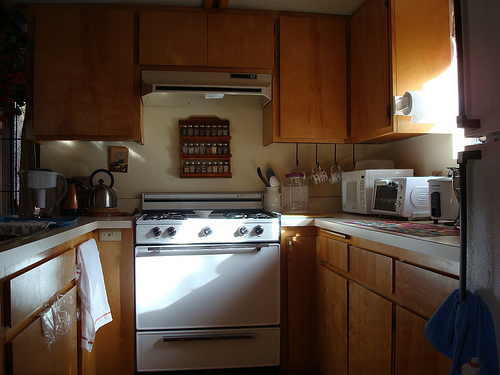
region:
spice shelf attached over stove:
[168, 102, 244, 186]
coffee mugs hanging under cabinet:
[301, 155, 374, 196]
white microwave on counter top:
[336, 160, 387, 211]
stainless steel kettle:
[76, 162, 133, 225]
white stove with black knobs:
[127, 170, 293, 374]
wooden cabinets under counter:
[285, 215, 453, 373]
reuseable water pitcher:
[11, 157, 76, 223]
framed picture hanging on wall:
[100, 140, 140, 180]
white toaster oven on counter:
[373, 172, 430, 225]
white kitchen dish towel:
[66, 234, 131, 351]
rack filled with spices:
[175, 109, 239, 186]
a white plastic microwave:
[339, 167, 411, 213]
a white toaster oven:
[369, 172, 441, 219]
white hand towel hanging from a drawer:
[71, 238, 113, 356]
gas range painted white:
[125, 188, 289, 373]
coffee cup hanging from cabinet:
[307, 161, 337, 188]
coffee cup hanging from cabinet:
[327, 163, 347, 184]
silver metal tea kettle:
[87, 163, 118, 213]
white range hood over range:
[137, 66, 276, 115]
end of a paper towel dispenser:
[392, 82, 433, 124]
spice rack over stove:
[163, 113, 248, 183]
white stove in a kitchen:
[119, 182, 309, 372]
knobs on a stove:
[150, 226, 282, 249]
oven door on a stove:
[124, 241, 286, 327]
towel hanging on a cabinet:
[66, 238, 118, 348]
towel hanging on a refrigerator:
[435, 261, 493, 365]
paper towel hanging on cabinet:
[395, 77, 466, 121]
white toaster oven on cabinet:
[371, 166, 436, 211]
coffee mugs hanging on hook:
[302, 156, 350, 194]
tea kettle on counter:
[85, 160, 126, 211]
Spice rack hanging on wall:
[172, 108, 239, 184]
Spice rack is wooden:
[174, 110, 239, 191]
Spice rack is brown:
[172, 109, 247, 184]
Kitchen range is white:
[136, 187, 293, 374]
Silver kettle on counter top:
[83, 160, 118, 217]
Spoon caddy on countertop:
[251, 157, 288, 217]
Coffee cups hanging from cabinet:
[311, 134, 345, 195]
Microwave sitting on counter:
[338, 159, 395, 221]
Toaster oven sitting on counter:
[367, 165, 429, 235]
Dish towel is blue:
[413, 242, 498, 367]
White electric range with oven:
[136, 195, 281, 370]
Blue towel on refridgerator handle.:
[408, 274, 498, 372]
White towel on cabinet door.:
[72, 239, 114, 352]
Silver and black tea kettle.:
[81, 164, 118, 217]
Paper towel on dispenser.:
[392, 85, 443, 117]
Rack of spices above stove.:
[169, 116, 242, 178]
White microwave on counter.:
[336, 167, 385, 212]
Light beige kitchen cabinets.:
[317, 241, 424, 366]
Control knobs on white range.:
[137, 224, 276, 236]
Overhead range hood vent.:
[142, 71, 273, 108]